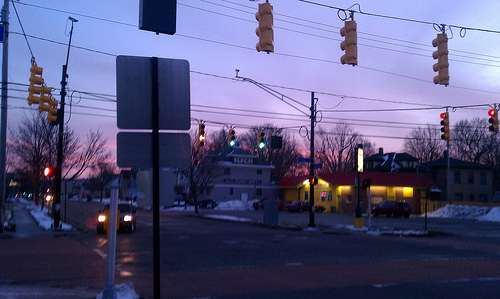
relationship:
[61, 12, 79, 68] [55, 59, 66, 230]
traffic camera on a pole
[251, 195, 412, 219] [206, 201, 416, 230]
cars are in parking lot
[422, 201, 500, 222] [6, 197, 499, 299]
snow on ground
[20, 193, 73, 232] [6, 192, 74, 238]
snow on sidewalk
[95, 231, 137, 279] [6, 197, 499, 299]
reflection of lights are on street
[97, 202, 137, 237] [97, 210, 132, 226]
car has on car headlights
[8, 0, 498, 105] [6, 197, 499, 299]
wires above street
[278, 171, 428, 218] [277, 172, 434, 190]
building has a top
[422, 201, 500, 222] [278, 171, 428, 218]
snow in front of store